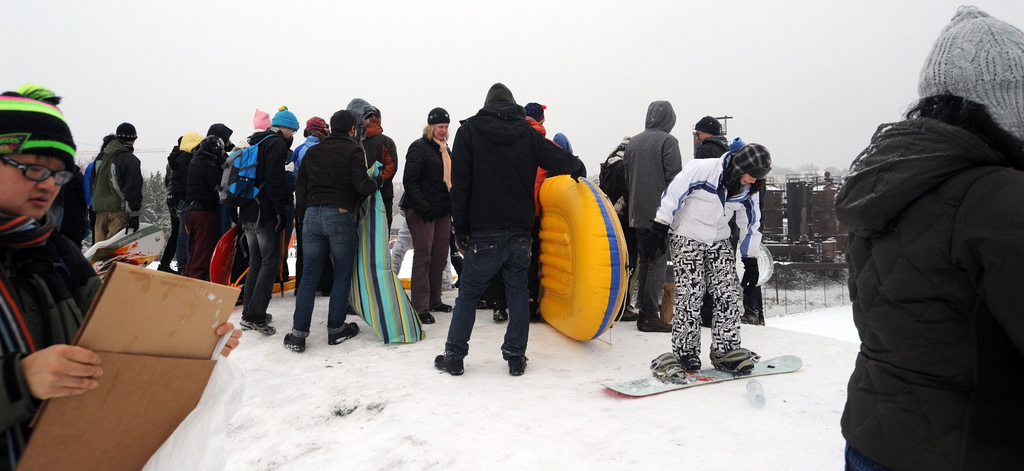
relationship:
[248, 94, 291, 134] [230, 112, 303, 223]
cap on child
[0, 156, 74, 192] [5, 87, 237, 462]
glasses on man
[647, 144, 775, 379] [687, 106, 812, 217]
boy on hat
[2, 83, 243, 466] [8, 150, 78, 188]
boy wearing glasses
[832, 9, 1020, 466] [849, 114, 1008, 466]
person in jacket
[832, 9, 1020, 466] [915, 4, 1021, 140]
person in beanie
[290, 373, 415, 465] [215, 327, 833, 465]
footprints in snow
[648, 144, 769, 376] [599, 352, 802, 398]
boy on snowboard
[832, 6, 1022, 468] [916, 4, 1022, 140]
girl wearing beanie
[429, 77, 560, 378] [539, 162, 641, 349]
man holding raft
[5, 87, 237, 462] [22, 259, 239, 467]
man looking at box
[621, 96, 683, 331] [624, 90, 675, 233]
man wearing coat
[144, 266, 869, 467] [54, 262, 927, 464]
snow on ground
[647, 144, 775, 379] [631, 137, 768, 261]
boy wearing white coat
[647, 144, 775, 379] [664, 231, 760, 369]
boy wearing pants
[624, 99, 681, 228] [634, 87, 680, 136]
coat with hood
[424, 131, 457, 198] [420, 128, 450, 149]
scarf around woman's neck